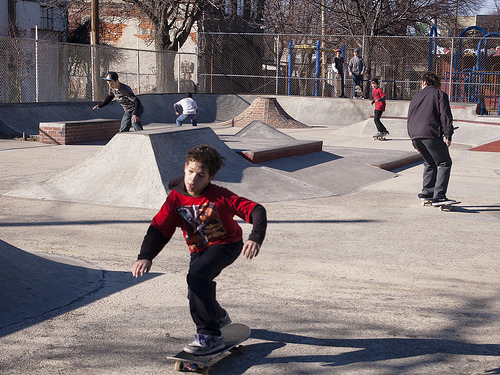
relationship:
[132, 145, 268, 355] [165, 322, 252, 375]
boy on skateboard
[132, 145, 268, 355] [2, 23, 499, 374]
boy in park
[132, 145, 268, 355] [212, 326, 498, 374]
boy has shadow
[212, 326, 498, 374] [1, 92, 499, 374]
shadow on ground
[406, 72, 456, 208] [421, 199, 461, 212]
man on skateboard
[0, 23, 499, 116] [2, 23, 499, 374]
fence behind park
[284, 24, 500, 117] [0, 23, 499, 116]
playground behind fence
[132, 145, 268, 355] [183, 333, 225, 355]
boy has foot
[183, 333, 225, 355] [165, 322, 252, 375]
foot on skateboard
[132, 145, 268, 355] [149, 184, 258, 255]
boy wearing shirt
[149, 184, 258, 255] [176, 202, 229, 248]
shirt has cartoons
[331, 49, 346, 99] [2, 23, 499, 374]
boy on side of park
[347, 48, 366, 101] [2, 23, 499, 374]
boy on side of park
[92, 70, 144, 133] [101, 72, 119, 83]
person wearing hat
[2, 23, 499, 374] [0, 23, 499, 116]
park has fence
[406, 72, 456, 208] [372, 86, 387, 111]
man wearing shirt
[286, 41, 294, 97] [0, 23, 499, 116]
pole part of fence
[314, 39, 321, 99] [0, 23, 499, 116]
pole part of fence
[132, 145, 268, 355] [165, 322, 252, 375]
boy riding skateboard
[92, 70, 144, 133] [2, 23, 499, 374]
person in park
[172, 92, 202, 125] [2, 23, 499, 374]
person in park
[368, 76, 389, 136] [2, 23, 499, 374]
person in park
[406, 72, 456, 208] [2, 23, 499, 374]
man in park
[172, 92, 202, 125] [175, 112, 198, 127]
person wearing jeans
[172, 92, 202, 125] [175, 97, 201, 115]
person wearing t-shirt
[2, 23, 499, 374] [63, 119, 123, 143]
park has grind rail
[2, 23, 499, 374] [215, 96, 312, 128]
park has half pipe section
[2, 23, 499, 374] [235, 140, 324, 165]
park has grinding wall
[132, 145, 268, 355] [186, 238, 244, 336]
boy wearing pants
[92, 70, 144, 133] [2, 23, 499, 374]
person at park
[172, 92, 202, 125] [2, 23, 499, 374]
person at park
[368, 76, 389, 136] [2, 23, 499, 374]
person at park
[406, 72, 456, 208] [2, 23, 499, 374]
man at park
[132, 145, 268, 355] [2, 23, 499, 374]
boy at park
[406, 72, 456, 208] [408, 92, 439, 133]
man has back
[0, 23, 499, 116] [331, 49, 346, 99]
fence behind boy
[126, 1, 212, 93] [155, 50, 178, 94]
tree has trunk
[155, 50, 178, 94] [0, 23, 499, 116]
trunk behind fence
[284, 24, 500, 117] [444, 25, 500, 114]
playground has equipment